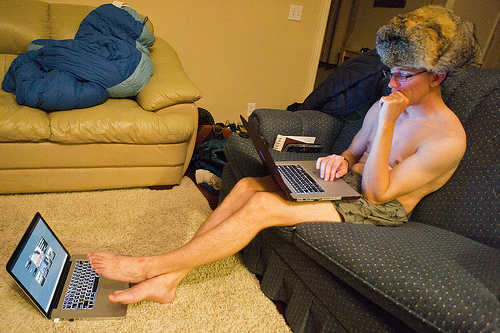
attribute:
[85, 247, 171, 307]
feet — MAN'S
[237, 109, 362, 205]
laptop — silver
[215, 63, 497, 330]
couch — blue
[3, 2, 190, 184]
couch — BEIGE, COMFORTABLE, GREY, SPOTTED, SECOND, CREAM, blue, leather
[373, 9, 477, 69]
hat — FURRY, FUR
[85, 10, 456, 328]
man — SHIRTLESS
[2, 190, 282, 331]
rug — white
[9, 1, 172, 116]
blanket — blue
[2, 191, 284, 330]
carpet — beige, white, fluffy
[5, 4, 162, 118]
bag — blue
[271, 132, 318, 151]
papers — stuffed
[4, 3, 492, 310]
room — untidy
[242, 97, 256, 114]
outlet — electrical